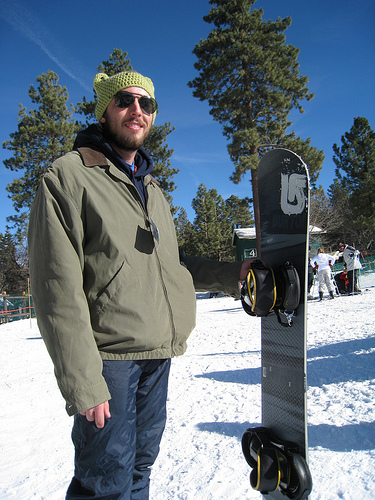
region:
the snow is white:
[174, 423, 200, 485]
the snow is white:
[188, 473, 193, 490]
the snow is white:
[170, 426, 215, 497]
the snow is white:
[166, 389, 215, 483]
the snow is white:
[206, 469, 210, 494]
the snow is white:
[187, 383, 228, 486]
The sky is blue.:
[323, 8, 373, 95]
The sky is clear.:
[320, 13, 373, 90]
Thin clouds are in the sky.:
[180, 124, 214, 175]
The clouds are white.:
[182, 125, 220, 177]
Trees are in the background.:
[187, 4, 317, 135]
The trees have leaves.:
[176, 17, 312, 137]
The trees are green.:
[179, 21, 317, 126]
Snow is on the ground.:
[179, 444, 221, 493]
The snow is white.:
[189, 443, 229, 498]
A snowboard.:
[230, 131, 321, 498]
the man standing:
[25, 65, 201, 495]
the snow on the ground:
[162, 436, 224, 498]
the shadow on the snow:
[308, 328, 372, 486]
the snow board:
[244, 144, 321, 494]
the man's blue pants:
[54, 348, 170, 493]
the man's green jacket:
[30, 140, 197, 412]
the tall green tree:
[185, 4, 336, 309]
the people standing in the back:
[306, 227, 360, 302]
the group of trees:
[5, 47, 253, 316]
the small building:
[226, 217, 329, 293]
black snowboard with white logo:
[243, 149, 318, 497]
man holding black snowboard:
[40, 68, 320, 496]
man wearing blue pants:
[35, 70, 203, 494]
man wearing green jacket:
[29, 70, 192, 496]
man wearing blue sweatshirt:
[27, 65, 198, 498]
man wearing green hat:
[35, 70, 198, 495]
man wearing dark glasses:
[33, 69, 201, 497]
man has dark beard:
[38, 69, 196, 495]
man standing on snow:
[37, 69, 231, 497]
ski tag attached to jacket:
[32, 148, 195, 354]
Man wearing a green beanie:
[85, 62, 179, 139]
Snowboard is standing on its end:
[223, 120, 341, 496]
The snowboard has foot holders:
[234, 429, 300, 494]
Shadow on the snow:
[316, 331, 372, 459]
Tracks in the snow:
[187, 388, 230, 492]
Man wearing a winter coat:
[18, 146, 225, 415]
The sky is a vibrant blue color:
[118, 18, 181, 67]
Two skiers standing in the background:
[312, 242, 370, 301]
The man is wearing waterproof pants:
[63, 366, 202, 498]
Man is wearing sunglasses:
[109, 84, 168, 118]